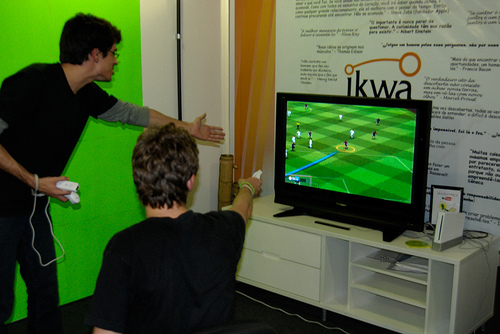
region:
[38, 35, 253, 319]
Two men playing the wii game.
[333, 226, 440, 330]
Shelves on the desk.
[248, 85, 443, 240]
Television sitting on the table.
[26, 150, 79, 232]
Wii controller in man hand.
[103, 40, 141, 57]
The man is wearing glasses.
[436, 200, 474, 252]
Wii game console on the white table.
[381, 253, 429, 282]
Paper on the shelves.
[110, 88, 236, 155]
The man arm is stretched out.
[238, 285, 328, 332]
A white cord on the floor.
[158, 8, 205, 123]
A black cord on the wall.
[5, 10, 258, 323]
two men with game controls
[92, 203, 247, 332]
black short sleeve tee shirt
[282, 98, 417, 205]
image on television screen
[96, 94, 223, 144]
gray sleeve on arm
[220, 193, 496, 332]
white table with shelves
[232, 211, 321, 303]
two drawers of table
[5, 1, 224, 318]
green and white wall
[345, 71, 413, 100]
four black letters on white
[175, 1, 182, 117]
long black thin pole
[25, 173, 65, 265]
wire on man's wrist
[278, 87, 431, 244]
Small black TV set on a white cabinet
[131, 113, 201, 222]
Wavy brown hair cut short length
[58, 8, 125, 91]
Man with black hair and black framed glasses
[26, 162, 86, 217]
White game controller being held and connected by a wire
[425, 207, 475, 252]
White Wii game console with a gray colored base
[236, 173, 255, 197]
Green wrist band on a man's arm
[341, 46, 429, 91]
Orange colored logo above a name in black letters on a white background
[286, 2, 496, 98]
White wall covered in black colored writing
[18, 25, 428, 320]
Two men holding white game controllers looking at a TV screen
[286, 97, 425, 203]
Screen displaying a video game being played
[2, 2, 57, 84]
The wall is green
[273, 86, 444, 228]
Th tv is on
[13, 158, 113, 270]
The man has a controller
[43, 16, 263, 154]
The man's arm is extended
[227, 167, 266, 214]
The man has bracelet on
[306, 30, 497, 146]
The wall has words on it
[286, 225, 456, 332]
The tv stand is white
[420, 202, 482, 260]
The game console is a Wii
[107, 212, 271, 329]
The person's shirt is black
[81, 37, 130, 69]
The man has glasses on